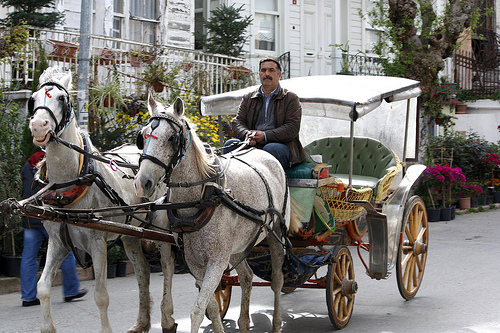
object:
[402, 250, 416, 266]
spokes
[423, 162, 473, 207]
flower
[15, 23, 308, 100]
gate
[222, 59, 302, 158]
man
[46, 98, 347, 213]
reins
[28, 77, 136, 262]
horse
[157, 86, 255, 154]
flowers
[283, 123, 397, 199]
seat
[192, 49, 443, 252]
cart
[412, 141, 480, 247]
flowers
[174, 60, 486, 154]
roof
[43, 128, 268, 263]
strap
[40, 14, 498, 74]
building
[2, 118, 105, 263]
person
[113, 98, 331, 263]
horse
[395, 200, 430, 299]
wheel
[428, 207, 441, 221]
vase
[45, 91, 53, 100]
spot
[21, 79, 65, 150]
face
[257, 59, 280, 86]
face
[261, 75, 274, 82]
mustache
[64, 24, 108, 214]
pole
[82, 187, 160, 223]
rod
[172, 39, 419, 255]
carriage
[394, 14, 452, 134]
tree